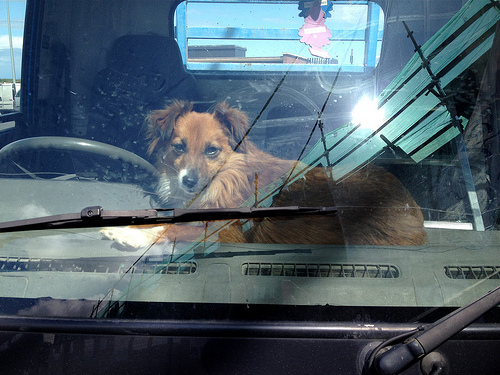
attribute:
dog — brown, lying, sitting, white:
[104, 100, 429, 252]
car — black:
[0, 1, 496, 372]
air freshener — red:
[300, 7, 332, 51]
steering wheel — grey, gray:
[3, 136, 163, 193]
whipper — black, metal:
[0, 203, 338, 230]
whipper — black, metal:
[363, 287, 494, 375]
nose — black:
[183, 172, 197, 186]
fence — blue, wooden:
[1, 3, 383, 83]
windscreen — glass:
[1, 2, 495, 322]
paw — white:
[99, 224, 161, 252]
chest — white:
[156, 170, 181, 213]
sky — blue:
[0, 4, 383, 58]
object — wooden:
[186, 43, 309, 63]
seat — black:
[87, 32, 198, 145]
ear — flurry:
[214, 98, 249, 155]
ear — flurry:
[142, 97, 192, 156]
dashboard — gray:
[1, 175, 499, 304]